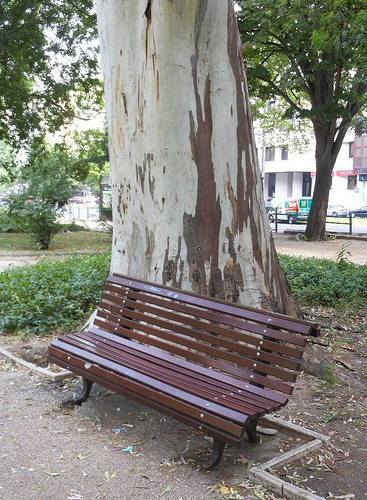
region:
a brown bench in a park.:
[44, 271, 325, 475]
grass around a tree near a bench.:
[0, 250, 364, 326]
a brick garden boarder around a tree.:
[0, 332, 334, 499]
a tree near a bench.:
[92, 0, 316, 377]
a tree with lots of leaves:
[231, 1, 365, 239]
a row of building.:
[0, 67, 365, 237]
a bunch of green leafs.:
[2, 0, 115, 245]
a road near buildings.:
[266, 214, 365, 237]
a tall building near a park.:
[24, 79, 111, 229]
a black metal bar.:
[59, 371, 102, 416]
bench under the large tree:
[42, 243, 327, 478]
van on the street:
[271, 180, 325, 219]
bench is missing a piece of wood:
[77, 356, 95, 371]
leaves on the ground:
[279, 408, 357, 498]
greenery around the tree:
[12, 253, 98, 332]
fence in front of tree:
[266, 199, 365, 240]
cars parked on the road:
[322, 196, 365, 222]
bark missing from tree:
[180, 78, 254, 285]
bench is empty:
[60, 258, 324, 489]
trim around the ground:
[253, 412, 305, 497]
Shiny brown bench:
[39, 269, 322, 474]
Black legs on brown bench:
[68, 374, 284, 481]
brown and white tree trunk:
[81, 0, 309, 412]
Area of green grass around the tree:
[1, 242, 366, 368]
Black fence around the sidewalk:
[262, 195, 357, 241]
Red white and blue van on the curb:
[262, 193, 323, 229]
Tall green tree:
[231, 2, 366, 248]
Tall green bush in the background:
[4, 137, 86, 262]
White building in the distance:
[234, 72, 365, 247]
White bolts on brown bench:
[189, 312, 282, 445]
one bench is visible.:
[46, 261, 322, 453]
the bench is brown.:
[43, 267, 334, 466]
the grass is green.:
[0, 253, 116, 334]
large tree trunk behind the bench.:
[86, 2, 318, 348]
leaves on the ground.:
[0, 305, 363, 494]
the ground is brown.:
[1, 353, 264, 499]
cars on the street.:
[263, 189, 365, 227]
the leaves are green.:
[233, 2, 366, 132]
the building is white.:
[250, 99, 365, 214]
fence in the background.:
[268, 205, 360, 235]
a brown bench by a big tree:
[48, 272, 324, 470]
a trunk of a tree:
[98, 0, 287, 316]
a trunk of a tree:
[303, 134, 339, 241]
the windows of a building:
[263, 144, 294, 159]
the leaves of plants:
[30, 266, 87, 310]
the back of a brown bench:
[87, 272, 315, 373]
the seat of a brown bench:
[44, 331, 278, 444]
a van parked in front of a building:
[268, 190, 316, 225]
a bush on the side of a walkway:
[13, 194, 66, 250]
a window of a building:
[299, 170, 315, 196]